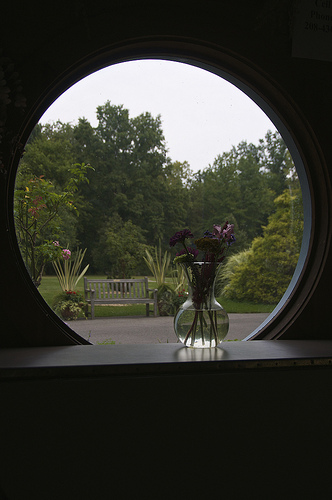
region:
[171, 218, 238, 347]
a vase of differently colored flowers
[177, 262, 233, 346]
a vase with a narrow opening and bulbous bottom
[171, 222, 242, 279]
pink, purple, and green flowers in a vase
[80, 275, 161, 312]
a wooden bench outside in a garden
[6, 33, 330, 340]
a circular window overlooking a garden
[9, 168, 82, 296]
a tree with red leaves and pink flowers outside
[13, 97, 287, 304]
lots of green trees outside in the garden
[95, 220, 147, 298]
a little green tree in the middle of a garden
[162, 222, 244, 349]
a flower-filled vase half-filled with water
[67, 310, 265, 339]
pavement on the edge of the garden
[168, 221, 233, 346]
purple flowers in a vase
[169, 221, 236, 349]
glass vase holding flowers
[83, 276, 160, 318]
wooden bench with vertical slats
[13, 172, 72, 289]
pink and red blossoms on a tree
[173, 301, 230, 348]
water distorting flower stems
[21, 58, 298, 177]
grey cloudy sky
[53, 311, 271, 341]
gravel driveway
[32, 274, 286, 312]
green grass in a yard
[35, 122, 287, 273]
tall tree line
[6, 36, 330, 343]
large circular window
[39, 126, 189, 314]
Looks like a park or garden.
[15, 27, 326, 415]
Round window with dark interior focuses and frames the outdoor scene.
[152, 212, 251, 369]
Fresh flowers.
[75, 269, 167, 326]
A place to sit.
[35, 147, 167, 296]
A good summer scene.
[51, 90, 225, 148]
Sky looks cloudy.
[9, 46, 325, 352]
Large round windows are not typical.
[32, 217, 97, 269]
Pink flowers are blooming.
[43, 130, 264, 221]
Plenty of trees in the background.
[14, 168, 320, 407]
Good use of lighting.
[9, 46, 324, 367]
view through round window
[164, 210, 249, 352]
vase of flowers on window shelf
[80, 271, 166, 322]
wooden bench in garden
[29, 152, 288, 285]
tall trees in distance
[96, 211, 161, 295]
tall bush in yard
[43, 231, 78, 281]
lavender flower on bush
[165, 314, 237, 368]
light reflecting through water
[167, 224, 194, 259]
purple bloom on stem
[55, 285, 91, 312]
red flower in flower pot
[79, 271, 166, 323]
grey wooden cobbler's bench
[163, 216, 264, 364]
A flower in a water filled vase.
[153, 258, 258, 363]
A vase filled with water.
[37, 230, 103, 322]
flowers in a yard.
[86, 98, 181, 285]
leafy green trees in a forest.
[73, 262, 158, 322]
A wooden bench in a yard.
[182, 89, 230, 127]
A section of hazy sky.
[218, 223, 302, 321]
A leaf filled bush in a yard.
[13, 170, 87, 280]
flower and leaf filled plants.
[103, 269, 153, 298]
A section of walkway out in a yard.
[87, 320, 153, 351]
A section of paved walkway.